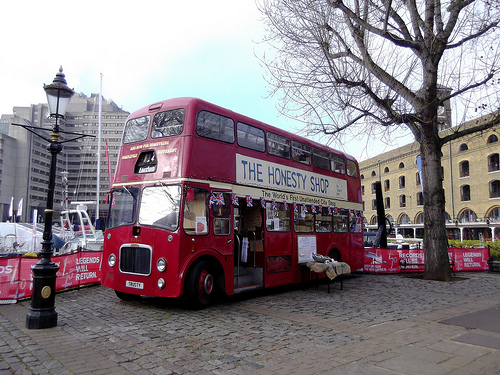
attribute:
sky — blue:
[2, 2, 499, 160]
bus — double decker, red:
[100, 98, 365, 308]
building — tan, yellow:
[359, 108, 499, 243]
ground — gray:
[1, 274, 499, 374]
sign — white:
[235, 154, 348, 202]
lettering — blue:
[240, 160, 329, 194]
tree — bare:
[255, 3, 491, 280]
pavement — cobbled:
[3, 271, 499, 375]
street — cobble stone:
[4, 271, 499, 375]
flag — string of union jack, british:
[210, 191, 222, 207]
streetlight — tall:
[12, 67, 98, 329]